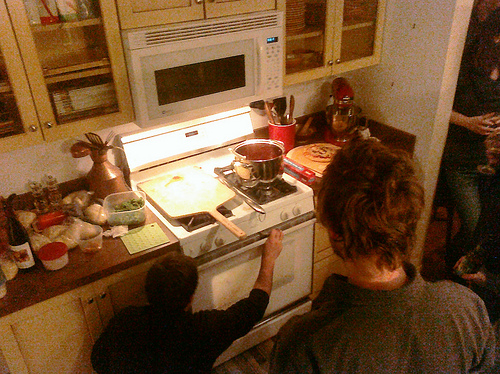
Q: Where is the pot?
A: On the stove.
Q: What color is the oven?
A: White.